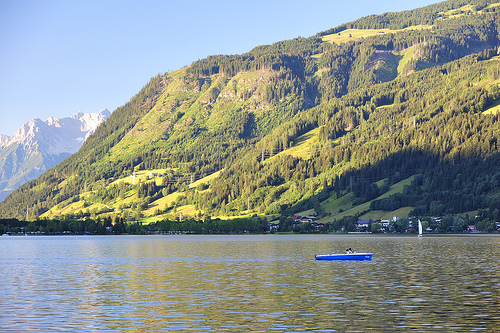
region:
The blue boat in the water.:
[314, 254, 373, 259]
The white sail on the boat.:
[415, 218, 422, 235]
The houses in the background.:
[285, 210, 487, 232]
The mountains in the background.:
[2, 113, 89, 185]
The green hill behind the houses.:
[0, 11, 497, 231]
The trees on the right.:
[380, 161, 498, 216]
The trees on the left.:
[3, 215, 270, 229]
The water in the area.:
[0, 234, 498, 331]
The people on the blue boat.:
[345, 248, 353, 255]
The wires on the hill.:
[132, 143, 318, 178]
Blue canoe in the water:
[311, 240, 378, 278]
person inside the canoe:
[341, 243, 359, 258]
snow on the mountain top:
[29, 104, 121, 150]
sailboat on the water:
[410, 218, 430, 240]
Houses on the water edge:
[287, 204, 492, 233]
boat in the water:
[302, 234, 394, 283]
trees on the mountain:
[181, 64, 426, 179]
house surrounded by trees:
[336, 213, 411, 235]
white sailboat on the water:
[411, 215, 427, 240]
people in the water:
[338, 243, 358, 262]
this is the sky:
[25, 12, 80, 32]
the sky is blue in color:
[175, 11, 240, 38]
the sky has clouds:
[37, 83, 82, 106]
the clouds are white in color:
[28, 93, 63, 110]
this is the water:
[43, 240, 191, 305]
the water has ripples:
[99, 260, 199, 290]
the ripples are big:
[166, 243, 283, 328]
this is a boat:
[313, 254, 379, 262]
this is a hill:
[261, 37, 409, 247]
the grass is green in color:
[174, 207, 190, 217]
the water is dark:
[12, 274, 498, 331]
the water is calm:
[55, 242, 186, 313]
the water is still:
[179, 243, 279, 328]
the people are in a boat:
[342, 242, 358, 254]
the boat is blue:
[306, 245, 375, 268]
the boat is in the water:
[307, 231, 384, 284]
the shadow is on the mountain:
[326, 120, 493, 215]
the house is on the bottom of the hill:
[357, 214, 370, 229]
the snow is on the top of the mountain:
[24, 104, 83, 144]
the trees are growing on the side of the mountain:
[330, 106, 474, 185]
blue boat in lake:
[316, 251, 371, 261]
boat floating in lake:
[316, 248, 371, 262]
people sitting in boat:
[343, 246, 354, 254]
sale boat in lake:
[417, 219, 424, 238]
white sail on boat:
[418, 220, 422, 233]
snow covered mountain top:
[3, 106, 109, 146]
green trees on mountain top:
[187, 35, 323, 68]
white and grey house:
[357, 218, 370, 228]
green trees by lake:
[1, 219, 266, 233]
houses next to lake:
[270, 216, 487, 236]